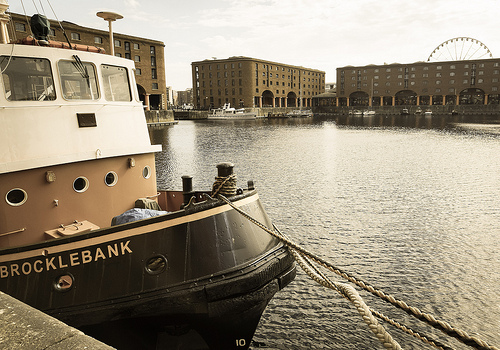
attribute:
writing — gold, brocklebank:
[0, 234, 133, 278]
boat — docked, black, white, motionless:
[0, 14, 304, 344]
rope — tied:
[205, 169, 494, 350]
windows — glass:
[4, 54, 133, 103]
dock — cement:
[4, 291, 127, 350]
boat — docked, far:
[209, 104, 260, 125]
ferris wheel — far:
[427, 37, 495, 60]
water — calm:
[156, 110, 499, 347]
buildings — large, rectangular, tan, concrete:
[195, 54, 496, 111]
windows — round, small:
[4, 161, 165, 209]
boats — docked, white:
[280, 99, 464, 119]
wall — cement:
[246, 98, 500, 117]